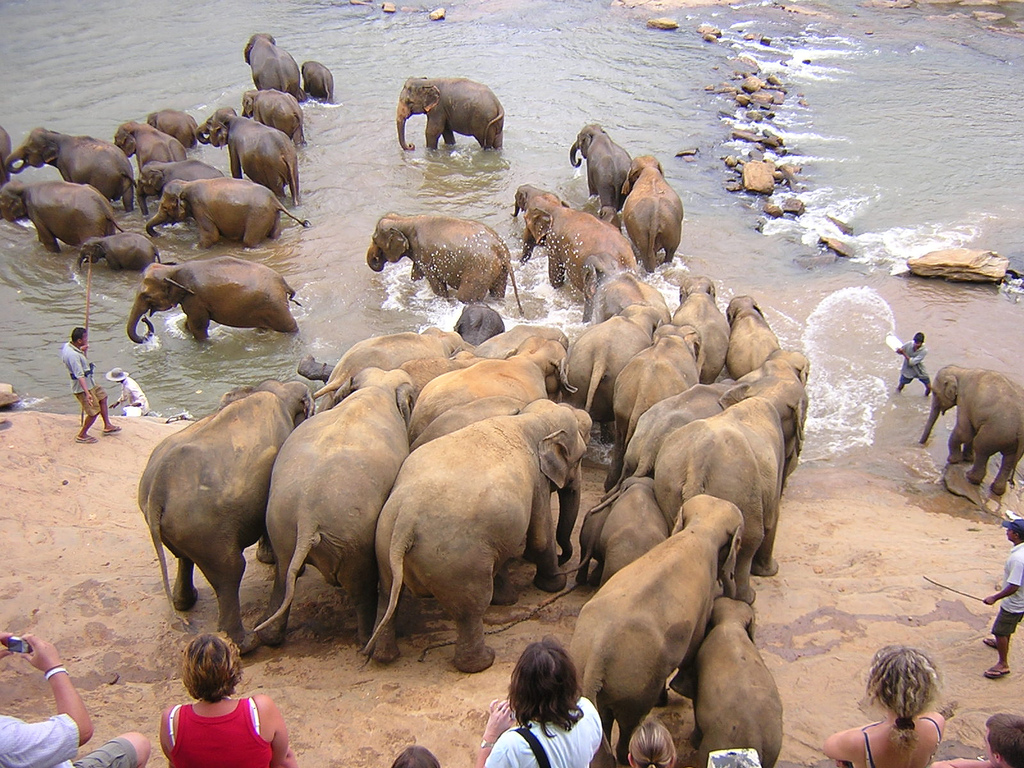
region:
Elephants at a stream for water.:
[7, 20, 1007, 736]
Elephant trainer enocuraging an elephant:
[879, 331, 941, 399]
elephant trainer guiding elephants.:
[943, 516, 1021, 685]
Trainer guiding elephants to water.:
[62, 320, 120, 447]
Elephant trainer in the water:
[105, 360, 153, 408]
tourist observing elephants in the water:
[153, 632, 300, 766]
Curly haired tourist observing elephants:
[822, 644, 958, 766]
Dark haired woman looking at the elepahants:
[482, 641, 604, 765]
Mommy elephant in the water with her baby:
[235, 32, 340, 103]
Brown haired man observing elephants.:
[964, 714, 1021, 766]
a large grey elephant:
[8, 165, 126, 242]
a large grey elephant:
[112, 112, 174, 177]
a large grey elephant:
[198, 101, 297, 204]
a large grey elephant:
[254, 77, 312, 150]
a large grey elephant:
[393, 67, 510, 148]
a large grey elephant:
[559, 118, 632, 198]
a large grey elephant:
[162, 359, 300, 571]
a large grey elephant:
[334, 294, 455, 400]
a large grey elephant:
[139, 367, 320, 633]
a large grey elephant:
[259, 360, 427, 667]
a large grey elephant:
[359, 406, 578, 685]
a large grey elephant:
[552, 500, 740, 741]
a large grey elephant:
[670, 382, 792, 597]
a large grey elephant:
[903, 352, 1020, 515]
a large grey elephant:
[426, 339, 586, 437]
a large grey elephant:
[362, 209, 530, 301]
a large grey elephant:
[390, 80, 509, 161]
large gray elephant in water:
[398, 63, 512, 177]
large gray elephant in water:
[356, 188, 509, 305]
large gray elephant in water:
[128, 252, 310, 341]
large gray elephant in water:
[211, 24, 329, 98]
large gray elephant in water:
[644, 346, 819, 493]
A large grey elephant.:
[364, 365, 583, 651]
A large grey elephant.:
[265, 345, 364, 634]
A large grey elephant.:
[138, 334, 294, 582]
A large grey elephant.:
[133, 248, 295, 359]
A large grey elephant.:
[166, 177, 284, 254]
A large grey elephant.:
[202, 98, 308, 213]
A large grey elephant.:
[234, 86, 317, 144]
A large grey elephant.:
[386, 55, 519, 167]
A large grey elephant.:
[561, 111, 635, 213]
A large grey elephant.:
[610, 153, 688, 277]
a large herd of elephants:
[5, 19, 1023, 763]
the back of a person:
[493, 617, 598, 763]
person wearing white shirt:
[490, 619, 609, 766]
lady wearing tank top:
[139, 607, 304, 766]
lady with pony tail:
[822, 614, 968, 766]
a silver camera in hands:
[0, 610, 67, 675]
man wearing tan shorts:
[57, 244, 127, 464]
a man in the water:
[881, 313, 946, 415]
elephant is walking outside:
[368, 150, 524, 388]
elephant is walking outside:
[90, 252, 261, 369]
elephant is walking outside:
[215, 164, 327, 291]